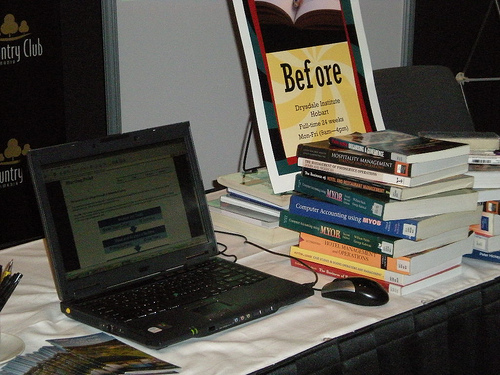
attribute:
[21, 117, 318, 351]
laptop — open, black, older model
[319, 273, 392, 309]
mouse — black, silver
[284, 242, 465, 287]
book — college book, soft cover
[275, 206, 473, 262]
book — college book, soft cover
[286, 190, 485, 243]
book — college book, soft cover, paperback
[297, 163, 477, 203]
book — college book, soft cover, paperback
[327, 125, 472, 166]
book — college book, soft cover, paperback